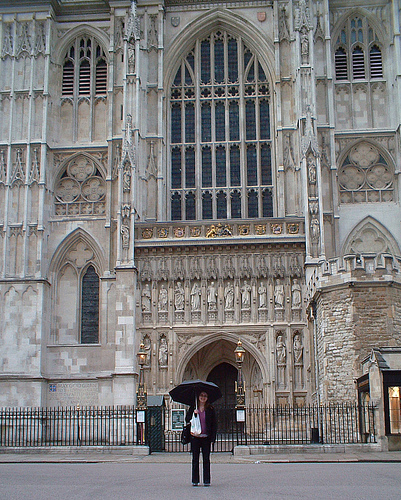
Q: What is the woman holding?
A: An umbrella.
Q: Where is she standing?
A: In front of the building.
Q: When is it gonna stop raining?
A: It did.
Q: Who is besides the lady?
A: Nobody.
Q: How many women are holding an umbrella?
A: 1.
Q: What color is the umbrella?
A: Black.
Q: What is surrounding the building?
A: A fence.